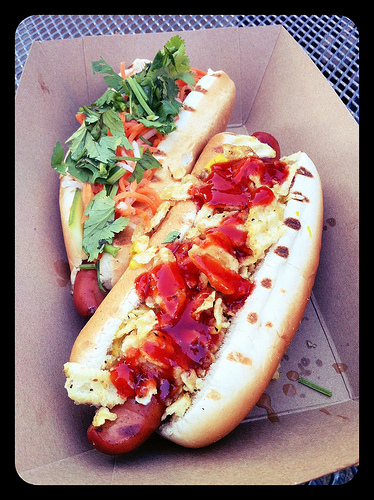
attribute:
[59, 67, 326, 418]
hotdogs — loaded 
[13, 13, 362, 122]
table — metal , wire 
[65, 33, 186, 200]
lettuce — green 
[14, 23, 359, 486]
box — brown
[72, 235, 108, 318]
hotdog — loaded 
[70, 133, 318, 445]
bun — white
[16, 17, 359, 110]
table — metal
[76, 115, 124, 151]
cilantro — green 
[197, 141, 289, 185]
mustard — dash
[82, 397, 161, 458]
hot dog — Chicago 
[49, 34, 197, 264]
cilantro — green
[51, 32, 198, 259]
leafy greens — few, leafy 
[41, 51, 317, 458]
hot dogs — brown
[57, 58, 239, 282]
bun — white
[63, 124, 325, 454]
hotdog — gourmet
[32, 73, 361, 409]
tray — cardboard 